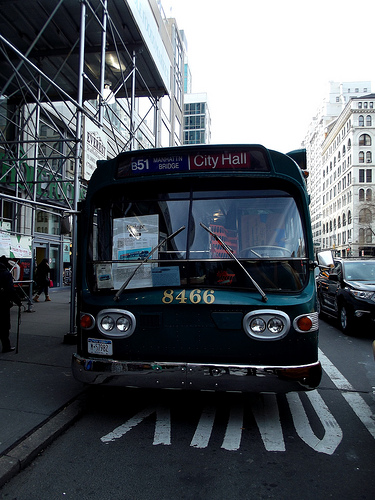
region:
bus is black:
[84, 161, 314, 384]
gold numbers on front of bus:
[157, 278, 221, 338]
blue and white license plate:
[78, 332, 122, 360]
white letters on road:
[84, 364, 373, 453]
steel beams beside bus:
[13, 29, 128, 354]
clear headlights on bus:
[97, 310, 129, 338]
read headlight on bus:
[68, 302, 92, 337]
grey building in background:
[311, 108, 358, 255]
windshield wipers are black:
[127, 202, 277, 287]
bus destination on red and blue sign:
[125, 150, 256, 171]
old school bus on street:
[70, 140, 320, 396]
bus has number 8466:
[161, 286, 215, 306]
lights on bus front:
[79, 306, 319, 337]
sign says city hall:
[111, 145, 273, 177]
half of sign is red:
[188, 150, 249, 170]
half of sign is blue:
[129, 154, 188, 175]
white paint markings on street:
[99, 340, 373, 455]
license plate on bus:
[87, 337, 114, 352]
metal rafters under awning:
[0, 0, 168, 345]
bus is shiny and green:
[77, 144, 318, 365]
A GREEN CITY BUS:
[74, 141, 320, 393]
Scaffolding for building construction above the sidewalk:
[0, 30, 158, 350]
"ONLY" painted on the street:
[100, 385, 346, 461]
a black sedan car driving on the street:
[319, 256, 374, 335]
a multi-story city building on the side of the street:
[304, 80, 374, 262]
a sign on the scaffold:
[82, 115, 110, 184]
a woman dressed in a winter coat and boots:
[32, 255, 57, 303]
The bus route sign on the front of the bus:
[115, 141, 257, 176]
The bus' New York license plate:
[84, 336, 114, 357]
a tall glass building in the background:
[181, 98, 212, 144]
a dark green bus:
[60, 137, 317, 399]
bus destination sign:
[123, 153, 253, 171]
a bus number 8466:
[154, 286, 214, 306]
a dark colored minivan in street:
[315, 255, 374, 333]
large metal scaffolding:
[4, 3, 167, 343]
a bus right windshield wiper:
[107, 222, 186, 299]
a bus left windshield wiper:
[197, 220, 268, 303]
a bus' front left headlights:
[248, 314, 282, 336]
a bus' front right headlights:
[98, 313, 130, 333]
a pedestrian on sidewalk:
[32, 257, 55, 302]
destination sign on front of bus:
[125, 147, 255, 172]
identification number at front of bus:
[159, 285, 222, 310]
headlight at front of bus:
[99, 308, 138, 339]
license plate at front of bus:
[86, 337, 117, 356]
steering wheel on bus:
[237, 234, 294, 265]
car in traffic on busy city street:
[318, 255, 373, 335]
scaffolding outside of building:
[26, 16, 170, 141]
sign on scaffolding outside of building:
[83, 122, 109, 180]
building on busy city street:
[316, 95, 374, 226]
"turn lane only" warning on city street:
[112, 402, 348, 481]